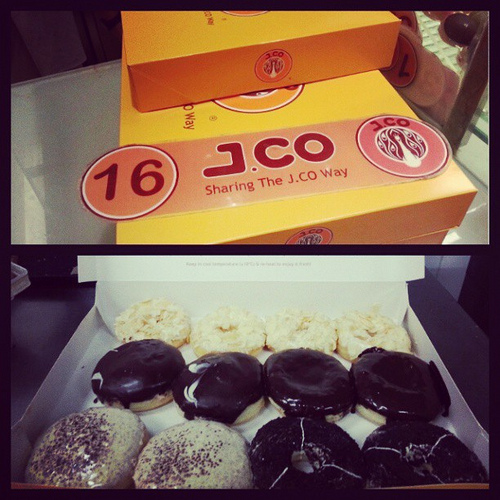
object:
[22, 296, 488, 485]
donuts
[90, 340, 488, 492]
donuts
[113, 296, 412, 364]
donuts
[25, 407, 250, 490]
donuts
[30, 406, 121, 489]
sprinkles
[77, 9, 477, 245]
box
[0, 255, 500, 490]
box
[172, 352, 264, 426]
chocolate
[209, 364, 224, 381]
hole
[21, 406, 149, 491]
donut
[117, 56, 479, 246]
table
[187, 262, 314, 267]
writing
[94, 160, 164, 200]
number 16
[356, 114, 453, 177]
logo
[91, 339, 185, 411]
donut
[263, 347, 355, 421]
donut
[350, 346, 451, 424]
donut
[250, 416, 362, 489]
donut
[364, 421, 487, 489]
donut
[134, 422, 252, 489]
white donut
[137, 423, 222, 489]
sprinkles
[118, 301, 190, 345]
white donut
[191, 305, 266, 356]
white donut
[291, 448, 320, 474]
hole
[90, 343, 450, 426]
donuts